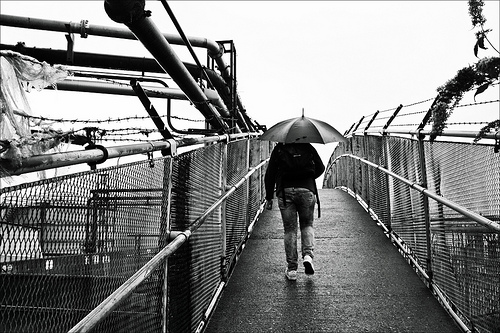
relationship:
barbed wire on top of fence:
[336, 71, 499, 138] [322, 136, 499, 329]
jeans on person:
[274, 188, 333, 270] [261, 117, 333, 285]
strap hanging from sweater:
[311, 189, 325, 226] [264, 140, 326, 201]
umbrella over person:
[255, 108, 348, 143] [264, 129, 326, 281]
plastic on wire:
[0, 48, 68, 166] [18, 111, 60, 124]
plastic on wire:
[3, 67, 61, 84] [19, 51, 41, 66]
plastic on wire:
[0, 48, 68, 166] [19, 51, 41, 66]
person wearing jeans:
[264, 124, 320, 284] [274, 188, 319, 271]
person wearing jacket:
[264, 129, 326, 281] [277, 152, 314, 194]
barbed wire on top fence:
[402, 96, 437, 108] [322, 130, 499, 312]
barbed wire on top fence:
[1, 50, 263, 150] [2, 131, 270, 331]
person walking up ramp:
[264, 129, 326, 281] [193, 188, 465, 331]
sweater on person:
[264, 140, 327, 201] [256, 133, 330, 273]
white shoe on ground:
[280, 266, 304, 292] [220, 205, 380, 330]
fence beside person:
[2, 131, 270, 331] [254, 107, 346, 281]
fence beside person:
[322, 92, 498, 331] [254, 107, 346, 281]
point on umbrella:
[298, 103, 305, 118] [257, 107, 349, 218]